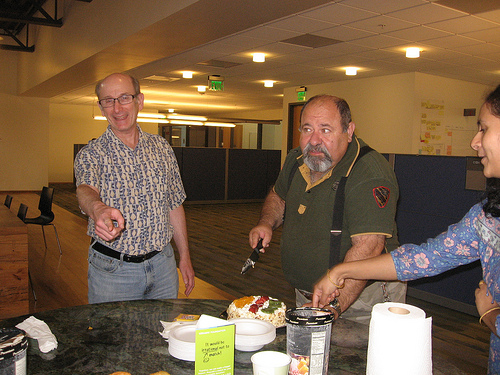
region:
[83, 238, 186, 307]
Man wearing pants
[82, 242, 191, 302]
Man is wearing pants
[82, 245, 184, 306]
Man wearing blue pants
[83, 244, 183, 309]
Man is wearing blue pants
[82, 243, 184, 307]
Man wearing light blue pants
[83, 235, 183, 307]
Man is wearing light blue pants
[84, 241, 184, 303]
Man wearing blue jeans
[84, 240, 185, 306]
Man is wearing blue jeans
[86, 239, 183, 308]
Man is wearing light blue jeans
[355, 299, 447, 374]
roll of white paper towels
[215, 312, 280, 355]
stack of white styrofoam plates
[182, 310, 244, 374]
table topper with green colored ad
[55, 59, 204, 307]
man of European descent pointing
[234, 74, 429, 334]
man of European descent cutting cake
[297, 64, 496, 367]
woman of Hispanic descent helping cut cake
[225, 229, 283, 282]
sharp knife used to cut cake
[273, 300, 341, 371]
half gallon of ice cream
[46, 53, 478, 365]
office celebration scene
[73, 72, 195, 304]
a man wearing blue jean pants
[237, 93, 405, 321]
a man looking toward the left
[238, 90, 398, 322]
a man holding a knife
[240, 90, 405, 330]
a man wearing suspenders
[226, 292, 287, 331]
a cake with white icing and fruit on top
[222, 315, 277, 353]
stack of Styrofoam bowls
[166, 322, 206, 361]
stack of Styrofoam plates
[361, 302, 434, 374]
a roll of white paper towels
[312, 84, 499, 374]
a woman wearing a purple floral patterned shirt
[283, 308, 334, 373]
a frosty container of ice cream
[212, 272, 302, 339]
a cake on the table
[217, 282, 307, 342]
a cake on the table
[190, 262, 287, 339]
a cake on the table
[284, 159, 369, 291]
man is wearing suspenders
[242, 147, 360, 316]
man is wearing suspenders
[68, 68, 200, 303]
Man with glasses pointing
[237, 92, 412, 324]
Man with grey beard cutting the cake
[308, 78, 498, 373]
Woman to the right of the men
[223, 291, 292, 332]
Cake sitting on the table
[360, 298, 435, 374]
Roll of paper towels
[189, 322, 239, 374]
Green sign on the table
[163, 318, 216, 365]
Stack of paper plates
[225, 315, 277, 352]
Stack of paper bowls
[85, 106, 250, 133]
Flourescent light strips in the back of the room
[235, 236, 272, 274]
Knife in the man's hand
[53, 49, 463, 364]
the men are standing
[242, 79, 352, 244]
the man is cutting a cake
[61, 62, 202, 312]
man with glasses pointing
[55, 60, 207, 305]
man with glasses pointing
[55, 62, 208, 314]
man with glasses pointing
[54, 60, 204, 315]
man with glasses pointing